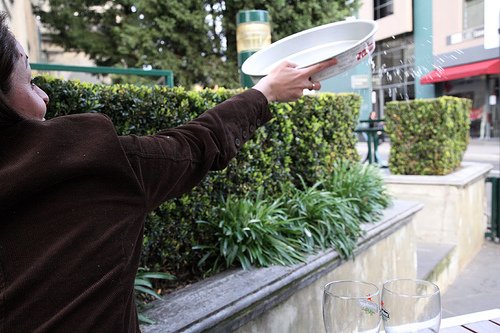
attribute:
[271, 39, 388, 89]
dish — white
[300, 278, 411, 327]
glasses — drinking, empty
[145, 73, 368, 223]
plants — green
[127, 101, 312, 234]
bushes — manicured, green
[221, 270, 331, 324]
wall — concrete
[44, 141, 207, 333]
jacket — brown, worn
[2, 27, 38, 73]
hair — brown, dark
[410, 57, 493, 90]
canopy — red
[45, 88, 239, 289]
woman — holding, sitting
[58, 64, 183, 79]
railing — metal, green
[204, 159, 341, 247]
shrubs — green, here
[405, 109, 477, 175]
grass — decorative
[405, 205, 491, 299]
steps — concrete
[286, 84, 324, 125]
hand — holding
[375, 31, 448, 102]
liquid — coming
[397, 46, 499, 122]
awning — red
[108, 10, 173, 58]
tree — green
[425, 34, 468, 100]
water — droplets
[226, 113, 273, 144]
buttons — brown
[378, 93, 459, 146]
bush — square-shaped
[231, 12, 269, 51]
light — cylinder-shaped